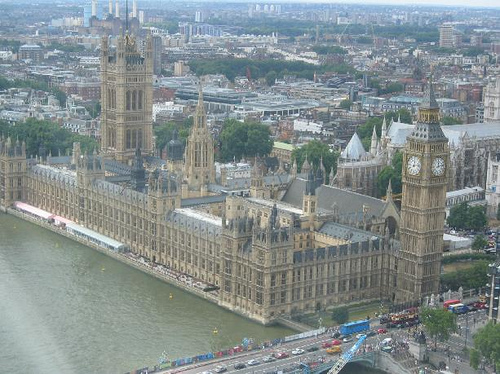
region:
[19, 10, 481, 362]
Towers in london and other buildings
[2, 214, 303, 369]
waterway next to the two towers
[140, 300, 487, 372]
highway by the waterway and clock tower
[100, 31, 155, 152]
tower one connected to the building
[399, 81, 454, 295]
tower two connected to the building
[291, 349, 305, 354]
car on the highway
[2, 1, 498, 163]
large city area behind the towers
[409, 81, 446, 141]
steeple on top of tower two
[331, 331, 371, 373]
crane in front of building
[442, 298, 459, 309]
double decker bus on highway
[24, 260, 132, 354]
The water looks calm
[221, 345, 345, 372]
A line of vehicles on the bridge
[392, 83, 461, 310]
A large clock tower by the road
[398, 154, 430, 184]
A large circular clock on the tower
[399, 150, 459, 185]
Two clock faces are on the building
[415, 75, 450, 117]
The pointed tip of the clock tower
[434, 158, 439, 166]
The hour hand of the clock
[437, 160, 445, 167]
The minute hand on the clock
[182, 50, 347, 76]
A grove of trees in the city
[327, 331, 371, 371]
A large blue crane by the road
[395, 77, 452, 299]
A tower in the photo.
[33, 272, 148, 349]
Water body in the photo.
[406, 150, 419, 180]
Clock in the photo.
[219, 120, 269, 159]
Trees in the photo.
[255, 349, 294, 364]
Cars in the photo.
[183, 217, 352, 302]
A building in the photo.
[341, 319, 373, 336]
A bus in the photo.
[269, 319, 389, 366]
A highway in the photo.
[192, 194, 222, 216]
A rooftop in the photo.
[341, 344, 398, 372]
A bridge in the photo.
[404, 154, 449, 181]
Clock faces on tower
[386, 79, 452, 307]
Right tower of building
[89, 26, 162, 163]
Left tower of building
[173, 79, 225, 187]
Tower on top of building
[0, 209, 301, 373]
Bluish green body of water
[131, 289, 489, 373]
Cars on a road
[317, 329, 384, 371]
Crane next to road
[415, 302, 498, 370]
Trees on side of road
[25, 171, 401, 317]
Windows on side of building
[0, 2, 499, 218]
Building in the distance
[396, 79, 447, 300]
The clock tower is tall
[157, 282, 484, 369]
There are many cars on the street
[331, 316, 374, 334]
The bus is blue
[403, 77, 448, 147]
The roof is grey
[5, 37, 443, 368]
Water next to the building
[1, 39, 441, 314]
The building is grey and tan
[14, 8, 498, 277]
Many buildings in the city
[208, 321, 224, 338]
Yellow buoy in the water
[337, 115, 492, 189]
The roof is white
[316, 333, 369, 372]
Blue and white crane